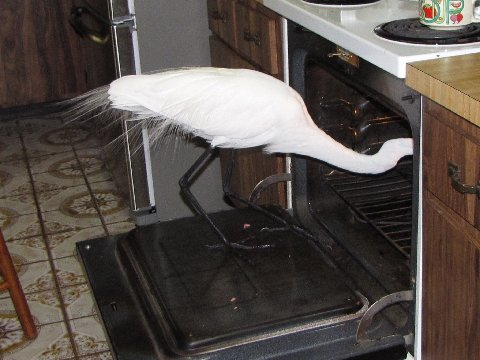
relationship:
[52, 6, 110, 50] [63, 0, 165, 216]
handle on door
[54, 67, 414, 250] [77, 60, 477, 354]
bird in oven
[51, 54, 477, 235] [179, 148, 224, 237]
bird has leg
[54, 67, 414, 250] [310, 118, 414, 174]
bird has neck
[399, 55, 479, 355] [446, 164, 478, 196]
cabinet has metal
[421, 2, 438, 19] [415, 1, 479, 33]
logo on cup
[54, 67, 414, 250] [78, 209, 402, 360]
bird standing on an door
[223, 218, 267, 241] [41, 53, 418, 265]
foot of bird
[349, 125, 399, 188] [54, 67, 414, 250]
neck of a bird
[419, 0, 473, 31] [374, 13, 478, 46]
cup on a burner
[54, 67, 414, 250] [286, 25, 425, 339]
bird looking into an open oven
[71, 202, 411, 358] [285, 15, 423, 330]
door of oven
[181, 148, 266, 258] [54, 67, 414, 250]
leg of bird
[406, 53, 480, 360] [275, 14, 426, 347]
cabinet next to oven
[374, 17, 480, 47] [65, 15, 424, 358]
burner sitting on oven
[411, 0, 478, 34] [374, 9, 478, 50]
cup sitting on burner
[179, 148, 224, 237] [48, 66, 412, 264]
leg of goose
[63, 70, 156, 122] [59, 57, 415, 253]
tail of goose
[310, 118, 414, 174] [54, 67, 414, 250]
neck of bird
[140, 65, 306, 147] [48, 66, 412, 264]
body of goose